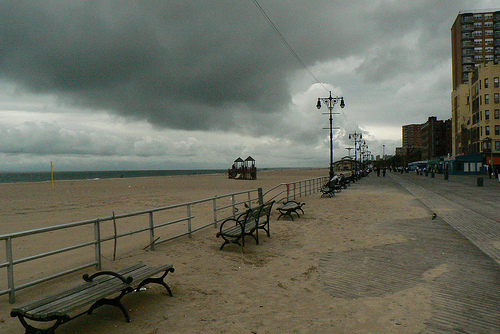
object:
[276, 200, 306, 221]
bench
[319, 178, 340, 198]
bench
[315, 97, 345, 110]
light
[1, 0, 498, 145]
clouds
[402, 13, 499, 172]
building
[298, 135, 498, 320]
sidewalk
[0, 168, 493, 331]
beach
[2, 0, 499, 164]
sky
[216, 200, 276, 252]
bench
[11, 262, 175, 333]
bench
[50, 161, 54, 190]
pole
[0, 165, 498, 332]
ground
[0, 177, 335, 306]
fence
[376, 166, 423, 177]
people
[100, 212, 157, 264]
gate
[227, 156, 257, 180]
play set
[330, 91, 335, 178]
light pole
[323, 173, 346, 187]
people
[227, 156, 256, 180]
hut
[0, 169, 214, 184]
ocean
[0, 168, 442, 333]
sand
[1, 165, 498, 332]
boardwalk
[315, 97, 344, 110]
street light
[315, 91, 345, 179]
streetlight